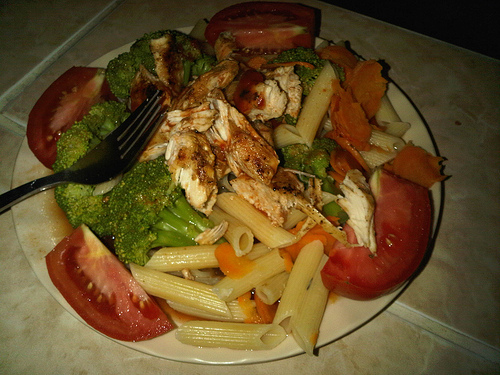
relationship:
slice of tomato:
[44, 221, 174, 343] [202, 0, 319, 57]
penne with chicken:
[280, 252, 315, 302] [213, 122, 247, 174]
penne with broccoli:
[280, 252, 315, 302] [119, 173, 211, 245]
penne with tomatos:
[280, 252, 315, 302] [65, 259, 110, 300]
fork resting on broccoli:
[0, 90, 172, 212] [52, 97, 224, 267]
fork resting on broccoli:
[0, 90, 172, 212] [57, 28, 361, 270]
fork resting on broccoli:
[0, 90, 172, 212] [278, 110, 348, 224]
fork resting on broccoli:
[0, 90, 172, 212] [270, 46, 347, 98]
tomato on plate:
[44, 227, 176, 349] [14, 25, 443, 352]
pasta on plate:
[123, 184, 363, 357] [14, 25, 443, 352]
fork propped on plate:
[0, 90, 172, 212] [14, 25, 443, 352]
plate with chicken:
[14, 25, 443, 352] [178, 109, 280, 194]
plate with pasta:
[14, 25, 443, 352] [149, 242, 329, 349]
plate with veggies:
[14, 25, 443, 352] [39, 76, 201, 328]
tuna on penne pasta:
[237, 67, 331, 177] [81, 64, 419, 354]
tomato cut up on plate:
[316, 175, 432, 303] [2, 18, 430, 365]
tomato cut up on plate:
[44, 227, 176, 349] [14, 25, 443, 352]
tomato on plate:
[316, 175, 432, 303] [14, 25, 443, 352]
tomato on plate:
[47, 227, 170, 349] [14, 25, 443, 352]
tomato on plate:
[27, 65, 107, 167] [14, 25, 443, 352]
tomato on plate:
[207, 6, 322, 51] [14, 25, 443, 352]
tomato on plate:
[316, 175, 432, 303] [13, 142, 414, 336]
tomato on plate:
[44, 227, 176, 349] [13, 142, 414, 336]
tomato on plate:
[348, 193, 405, 269] [41, 57, 481, 345]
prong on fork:
[117, 82, 175, 159] [26, 58, 181, 224]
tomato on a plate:
[32, 13, 413, 308] [14, 25, 443, 352]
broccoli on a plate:
[57, 28, 361, 270] [14, 25, 443, 352]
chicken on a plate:
[137, 58, 317, 213] [14, 25, 443, 352]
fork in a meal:
[0, 90, 172, 212] [92, 57, 397, 292]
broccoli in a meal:
[57, 28, 361, 270] [15, 28, 425, 373]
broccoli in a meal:
[246, 37, 378, 116] [15, 28, 425, 373]